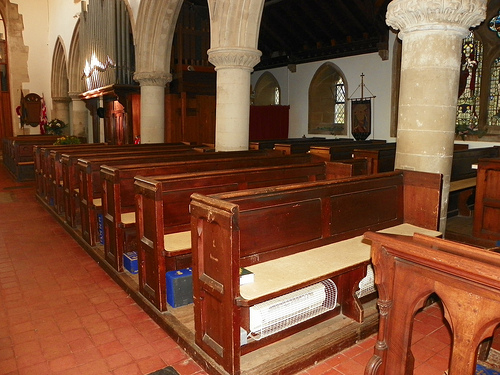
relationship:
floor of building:
[0, 174, 455, 371] [2, 3, 497, 372]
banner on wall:
[347, 69, 377, 141] [287, 58, 387, 139]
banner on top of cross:
[347, 72, 376, 141] [353, 74, 370, 99]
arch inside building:
[250, 77, 285, 106] [2, 3, 497, 372]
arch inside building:
[310, 63, 343, 135] [2, 3, 497, 372]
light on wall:
[79, 52, 118, 89] [46, 1, 141, 99]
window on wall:
[308, 61, 349, 141] [247, 45, 391, 144]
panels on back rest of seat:
[223, 169, 405, 267] [193, 194, 435, 338]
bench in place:
[186, 167, 444, 375] [16, 67, 423, 302]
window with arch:
[296, 44, 381, 144] [297, 61, 364, 98]